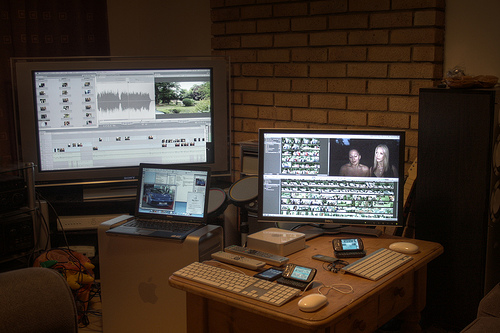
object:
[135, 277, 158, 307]
symbol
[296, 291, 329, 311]
mouse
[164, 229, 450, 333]
desk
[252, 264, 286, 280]
cell phone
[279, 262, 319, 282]
cell phone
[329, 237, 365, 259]
cell phone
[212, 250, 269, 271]
remotes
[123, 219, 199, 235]
keyboard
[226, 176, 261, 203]
drums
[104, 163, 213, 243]
laptop